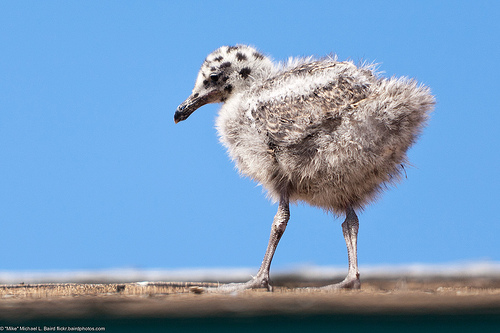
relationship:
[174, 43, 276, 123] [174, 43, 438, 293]
head of bird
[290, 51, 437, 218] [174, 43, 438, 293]
tail end of bird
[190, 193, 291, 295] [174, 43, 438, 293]
leg of bird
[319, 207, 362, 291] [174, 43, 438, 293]
leg of bird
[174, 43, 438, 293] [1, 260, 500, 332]
bird standing on ground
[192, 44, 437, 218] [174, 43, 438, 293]
fuzz on bird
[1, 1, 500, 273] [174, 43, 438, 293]
sky behind bird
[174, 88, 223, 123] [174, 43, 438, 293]
beak of bird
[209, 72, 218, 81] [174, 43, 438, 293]
eye of bird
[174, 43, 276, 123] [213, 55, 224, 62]
head has spot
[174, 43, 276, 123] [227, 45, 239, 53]
head has spot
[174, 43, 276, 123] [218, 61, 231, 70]
head has spot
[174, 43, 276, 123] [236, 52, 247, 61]
head has spot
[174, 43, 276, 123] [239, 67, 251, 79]
head has spot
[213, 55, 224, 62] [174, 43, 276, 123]
spot on head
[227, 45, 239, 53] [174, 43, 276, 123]
spot on head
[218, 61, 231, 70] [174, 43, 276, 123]
spot on head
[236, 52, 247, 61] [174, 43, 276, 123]
spot on head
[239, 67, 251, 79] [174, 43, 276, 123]
spot on head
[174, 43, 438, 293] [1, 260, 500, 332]
bird stands on ground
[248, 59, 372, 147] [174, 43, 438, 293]
wing of bird